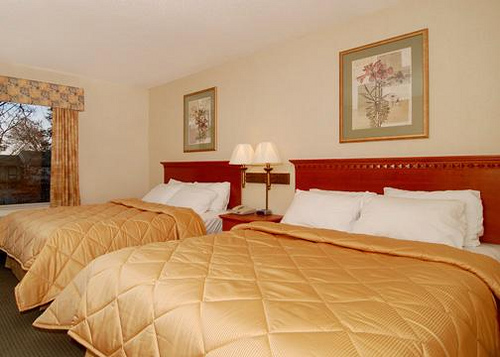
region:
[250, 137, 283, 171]
white lampshade with plastic protector covering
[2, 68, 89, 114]
tan and gray window valance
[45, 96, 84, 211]
tan drapes hanging on window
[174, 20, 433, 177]
matching matted and framed picture of flowers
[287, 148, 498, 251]
red wooden queen size headboard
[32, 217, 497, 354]
gold colored queen size comforter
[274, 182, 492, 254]
four white pillows on bed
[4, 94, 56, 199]
house and trees outside of room window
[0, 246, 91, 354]
olive colored carpet in room with gold comforter on bed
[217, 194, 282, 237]
red wooden end table in between two beds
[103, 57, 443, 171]
Pictures on the wall.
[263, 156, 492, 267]
Pillows on the bed.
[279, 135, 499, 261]
Headboard behind the bed.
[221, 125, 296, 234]
Lamps on the wall.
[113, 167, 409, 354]
Bedspread on the table.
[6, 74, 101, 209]
Curtains on the window.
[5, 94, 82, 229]
Window on the wall.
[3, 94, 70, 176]
Trees in the background.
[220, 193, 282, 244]
Phone on the nightstand.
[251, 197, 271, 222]
Clock on the nightstand.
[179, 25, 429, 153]
pictures hanging on wall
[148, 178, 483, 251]
pillows on bed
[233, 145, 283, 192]
a dual head gold frame lamp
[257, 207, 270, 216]
a small grey alarm clock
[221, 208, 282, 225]
a cherry wood colored nightstand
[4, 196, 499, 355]
gold comforters on bed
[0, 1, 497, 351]
a hotel room with two beds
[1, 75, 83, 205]
light beige colored curtains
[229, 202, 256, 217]
an off-white telephone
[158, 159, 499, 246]
cherry stained wooden headboards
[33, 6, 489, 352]
a nice motel room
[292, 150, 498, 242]
the headboard is red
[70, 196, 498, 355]
the bedspread is gold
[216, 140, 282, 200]
two lamps set in the middle of the beds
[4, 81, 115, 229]
gold curtains are at the window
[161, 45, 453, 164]
pictures are on the wall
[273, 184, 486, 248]
four pillows are on each bed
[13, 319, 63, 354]
the carpet is grey green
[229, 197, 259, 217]
a telephone sits on the night stand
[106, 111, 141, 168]
the walls are painted beige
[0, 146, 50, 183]
a house visible through a window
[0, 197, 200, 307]
a gold colored comforter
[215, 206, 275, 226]
a bed side table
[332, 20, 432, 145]
a picture on the wall above a bed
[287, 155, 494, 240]
a wooden headboard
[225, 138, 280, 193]
lamps on the wall between beds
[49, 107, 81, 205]
curtains alongside a window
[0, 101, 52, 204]
a window in a hotel room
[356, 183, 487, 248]
white pillows on a bed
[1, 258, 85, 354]
a carpet on a hotel room floor